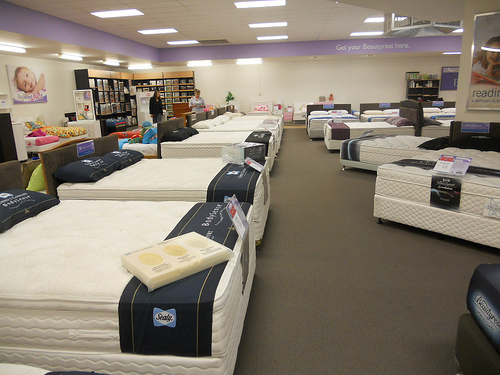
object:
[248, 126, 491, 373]
carpet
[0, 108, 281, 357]
mattress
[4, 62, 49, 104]
picture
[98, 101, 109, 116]
item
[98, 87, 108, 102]
item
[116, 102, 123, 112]
item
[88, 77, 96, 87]
item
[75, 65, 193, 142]
shelf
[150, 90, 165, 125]
person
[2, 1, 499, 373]
showroom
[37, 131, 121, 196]
headboard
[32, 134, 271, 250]
bed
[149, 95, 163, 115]
dark shirt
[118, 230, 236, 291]
object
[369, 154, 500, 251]
bed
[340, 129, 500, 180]
bed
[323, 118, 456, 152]
bed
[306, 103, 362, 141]
bed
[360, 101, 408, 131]
bed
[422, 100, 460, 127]
bed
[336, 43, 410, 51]
lettering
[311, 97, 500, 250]
mattress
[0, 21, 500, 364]
room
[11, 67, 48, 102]
baby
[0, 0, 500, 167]
wall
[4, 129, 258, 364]
mattresses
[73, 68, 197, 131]
bookshelves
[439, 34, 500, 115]
poster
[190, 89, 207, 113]
woman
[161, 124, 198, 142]
pillows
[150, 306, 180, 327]
logo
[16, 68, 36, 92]
face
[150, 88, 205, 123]
people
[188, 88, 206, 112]
people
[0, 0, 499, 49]
ceiling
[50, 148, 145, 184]
pillows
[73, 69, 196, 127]
display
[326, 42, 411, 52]
border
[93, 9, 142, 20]
light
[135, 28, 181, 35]
light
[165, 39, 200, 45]
light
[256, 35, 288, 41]
light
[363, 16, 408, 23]
light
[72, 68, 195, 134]
case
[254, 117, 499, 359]
floor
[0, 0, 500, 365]
store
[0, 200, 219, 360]
sheets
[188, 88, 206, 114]
customer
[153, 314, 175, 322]
words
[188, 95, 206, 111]
shirt